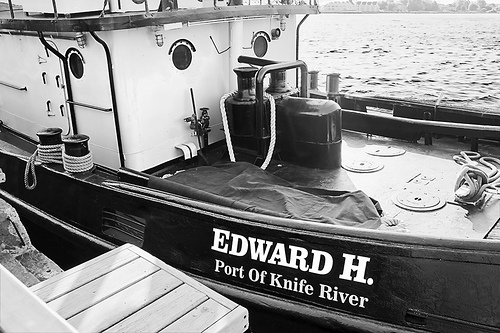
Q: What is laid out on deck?
A: Trap.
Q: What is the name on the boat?
A: Edward H.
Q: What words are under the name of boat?
A: Port of knife river.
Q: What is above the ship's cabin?
A: Roof.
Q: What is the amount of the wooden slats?
A: White.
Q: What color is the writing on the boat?
A: White.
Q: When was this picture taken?
A: During the day.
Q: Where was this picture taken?
A: At a dock.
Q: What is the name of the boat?
A: Edward H. Port of Knife River.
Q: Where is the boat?
A: In the water.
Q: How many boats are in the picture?
A: One.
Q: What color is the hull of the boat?
A: Black.